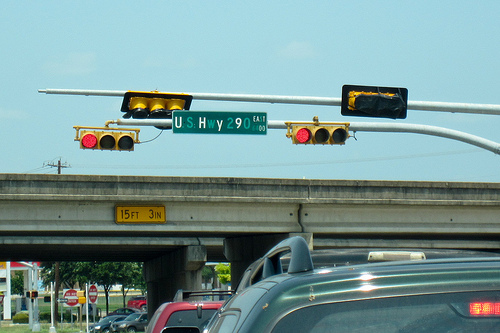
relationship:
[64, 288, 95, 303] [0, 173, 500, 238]
sign under bridge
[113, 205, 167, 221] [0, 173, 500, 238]
sign on bridge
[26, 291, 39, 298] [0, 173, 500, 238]
pedestrian sign under bridge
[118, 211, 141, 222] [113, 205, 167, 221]
black writing on yellow sign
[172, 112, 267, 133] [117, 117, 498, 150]
sign on pole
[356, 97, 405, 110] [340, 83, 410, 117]
black cover on traffic light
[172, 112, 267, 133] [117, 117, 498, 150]
street sign on pole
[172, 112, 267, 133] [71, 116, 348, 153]
sign between lights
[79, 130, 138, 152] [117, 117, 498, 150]
traffic light on pole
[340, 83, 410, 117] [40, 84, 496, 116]
traffic light on pole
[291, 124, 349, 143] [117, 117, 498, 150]
traffic light on pole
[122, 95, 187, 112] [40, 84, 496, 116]
street light attached to pole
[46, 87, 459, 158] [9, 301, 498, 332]
traffic signal above road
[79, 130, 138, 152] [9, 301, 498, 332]
traffic light above street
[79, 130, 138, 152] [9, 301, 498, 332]
traffic light over road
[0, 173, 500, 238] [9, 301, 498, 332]
bridge over road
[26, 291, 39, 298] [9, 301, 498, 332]
electronic sign on road